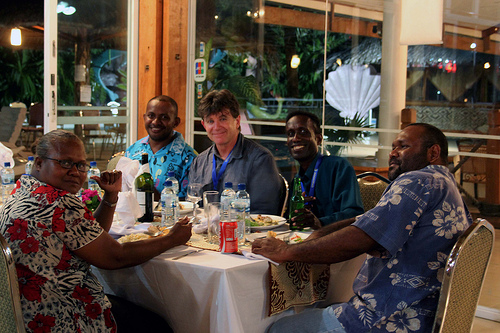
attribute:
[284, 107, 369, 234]
man — smiling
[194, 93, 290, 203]
male — white 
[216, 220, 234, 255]
can — Red 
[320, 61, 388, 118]
seashell — White 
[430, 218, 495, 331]
chair — SILVER, TAN 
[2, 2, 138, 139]
door — sliding, open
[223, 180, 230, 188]
cap — blue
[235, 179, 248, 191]
cap — blue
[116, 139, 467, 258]
shirts — BLUE 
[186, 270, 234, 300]
table cloth — white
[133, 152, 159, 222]
bottle — GREEN 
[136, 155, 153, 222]
bottle — green, glass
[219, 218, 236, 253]
can — red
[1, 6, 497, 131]
wall — back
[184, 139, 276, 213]
shirt — gray